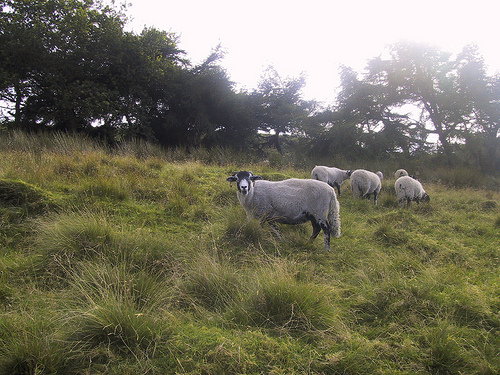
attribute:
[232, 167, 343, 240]
sheep — attentive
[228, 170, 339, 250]
sheep — standing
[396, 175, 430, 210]
sheep — grazing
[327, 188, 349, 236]
tail — long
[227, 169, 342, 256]
sheep — looking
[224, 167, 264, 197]
face — black, white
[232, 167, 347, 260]
sheep — not shorn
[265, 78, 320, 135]
leaves — green 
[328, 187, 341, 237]
tail — long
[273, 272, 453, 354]
grass — bushy, green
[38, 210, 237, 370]
grass — brown , green 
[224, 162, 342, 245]
herd — grazing, quiet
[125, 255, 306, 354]
grass — thick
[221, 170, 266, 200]
snout — white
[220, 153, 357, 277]
sheep — fascinated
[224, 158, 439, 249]
herd — undisturbed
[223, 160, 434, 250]
sheep — heavily coated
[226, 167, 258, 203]
head — white , black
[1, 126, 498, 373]
grass — green, long